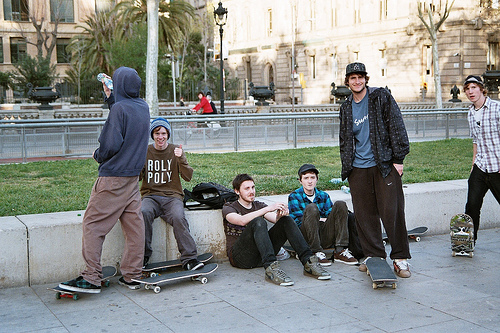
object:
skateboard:
[360, 250, 399, 291]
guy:
[219, 172, 333, 286]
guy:
[286, 163, 359, 268]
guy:
[61, 64, 152, 293]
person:
[202, 90, 218, 121]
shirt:
[194, 96, 214, 114]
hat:
[298, 164, 321, 174]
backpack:
[183, 179, 239, 211]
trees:
[180, 29, 206, 102]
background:
[0, 0, 499, 113]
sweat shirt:
[92, 67, 151, 178]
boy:
[138, 118, 204, 272]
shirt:
[139, 143, 194, 201]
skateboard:
[447, 212, 478, 258]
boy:
[460, 75, 500, 246]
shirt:
[463, 101, 499, 176]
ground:
[0, 225, 499, 332]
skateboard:
[130, 260, 220, 293]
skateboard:
[41, 263, 120, 302]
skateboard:
[138, 251, 214, 272]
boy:
[334, 61, 416, 278]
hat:
[342, 62, 368, 77]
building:
[200, 1, 500, 112]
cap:
[296, 164, 322, 175]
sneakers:
[57, 270, 104, 295]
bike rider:
[192, 92, 214, 134]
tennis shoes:
[264, 261, 297, 287]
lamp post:
[210, 1, 234, 132]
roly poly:
[145, 158, 174, 184]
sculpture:
[26, 82, 63, 110]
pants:
[464, 162, 499, 258]